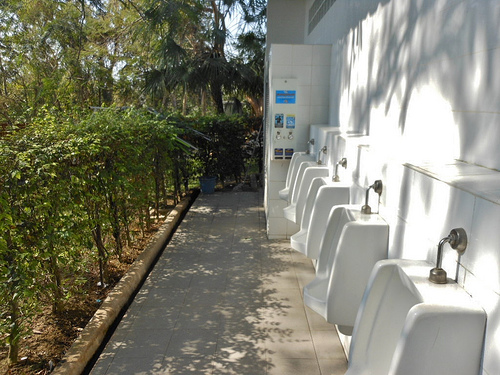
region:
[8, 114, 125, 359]
a line of trees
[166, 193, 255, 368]
a shadow of the trees on the ground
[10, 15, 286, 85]
tall trees in the background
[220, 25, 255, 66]
the sky through the trees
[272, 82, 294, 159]
a white sign on the wal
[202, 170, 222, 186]
a blue vase on the ground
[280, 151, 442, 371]
white urinals on the wall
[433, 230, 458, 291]
a silver pipe on the wall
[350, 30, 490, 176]
white tile on the wall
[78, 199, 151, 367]
a cement curb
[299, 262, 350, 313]
a urinal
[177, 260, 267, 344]
a shadow on the ground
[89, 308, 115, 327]
the curb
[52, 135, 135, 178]
the leaves on the tree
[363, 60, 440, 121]
a shadow on the wall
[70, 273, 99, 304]
the dirt on the ground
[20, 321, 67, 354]
the dirt is brown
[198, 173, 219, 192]
a bucket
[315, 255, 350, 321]
the urinal was white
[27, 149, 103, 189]
the leaves on the tree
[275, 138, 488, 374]
row of outdoor urinals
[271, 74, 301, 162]
condom dispenser on wall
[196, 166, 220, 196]
blue bucket holding a small tree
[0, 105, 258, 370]
hedge surrounding the toilet area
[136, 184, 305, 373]
tile flooring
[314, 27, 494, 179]
shadows of trees on white wall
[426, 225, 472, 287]
pipe for urinal water supply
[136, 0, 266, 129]
tree with palm leaves behind hedge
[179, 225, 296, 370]
shadow of hedge on ground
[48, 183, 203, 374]
curb separating plants from floor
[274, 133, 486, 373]
white urinals on exterior wall of building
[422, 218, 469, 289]
metla pipe attaching urinal to wall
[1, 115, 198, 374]
short green trees bordering paved walkway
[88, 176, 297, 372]
black shadows of foliage on ground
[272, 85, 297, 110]
blue sign on exterior wall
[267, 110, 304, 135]
two blue signs on side of wall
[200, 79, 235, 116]
brown tree trunk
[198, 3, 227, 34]
brown tree branches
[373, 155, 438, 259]
shadow of tree and tree trunk on white building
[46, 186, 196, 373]
cement sidewalk curb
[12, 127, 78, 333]
this is a tree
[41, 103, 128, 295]
this is a tree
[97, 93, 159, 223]
this is a tree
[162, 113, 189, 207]
this is a tree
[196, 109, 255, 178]
this is a tree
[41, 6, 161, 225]
this is a tree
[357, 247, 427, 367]
this is a urinal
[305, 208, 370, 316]
this is a urinal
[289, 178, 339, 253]
this is a urinal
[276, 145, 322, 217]
this is a urinal